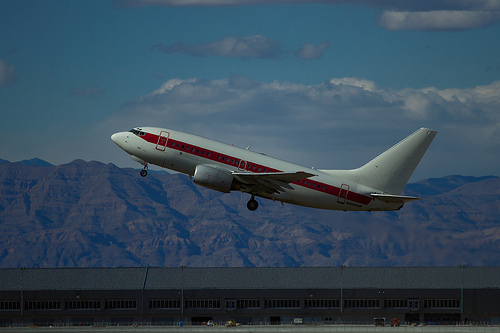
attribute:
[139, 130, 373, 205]
stripe — red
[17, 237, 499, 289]
roof — grey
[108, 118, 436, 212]
plane — commercial plane, white, red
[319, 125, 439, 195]
tail — white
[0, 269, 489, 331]
building — long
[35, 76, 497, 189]
cloud — big